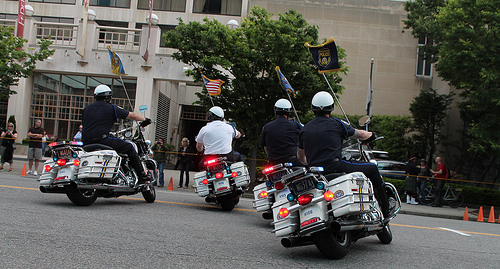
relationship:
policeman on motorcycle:
[71, 81, 152, 188] [35, 104, 159, 207]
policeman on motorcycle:
[258, 96, 305, 226] [251, 157, 311, 225]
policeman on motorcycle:
[80, 83, 157, 184] [244, 152, 441, 255]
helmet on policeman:
[273, 91, 300, 118] [264, 118, 299, 191]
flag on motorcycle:
[106, 43, 127, 76] [36, 116, 157, 207]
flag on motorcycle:
[276, 67, 298, 97] [191, 153, 251, 210]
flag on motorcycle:
[194, 70, 224, 97] [251, 159, 297, 221]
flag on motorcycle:
[106, 43, 127, 76] [269, 132, 403, 257]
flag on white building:
[11, 0, 36, 40] [1, 2, 248, 147]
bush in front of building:
[165, 6, 352, 121] [4, 1, 444, 177]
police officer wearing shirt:
[305, 105, 405, 208] [298, 112, 355, 162]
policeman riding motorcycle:
[80, 83, 157, 184] [36, 116, 157, 207]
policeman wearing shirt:
[194, 97, 243, 162] [193, 119, 240, 156]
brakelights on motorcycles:
[200, 173, 243, 180] [229, 152, 386, 247]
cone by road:
[487, 204, 496, 221] [14, 183, 254, 264]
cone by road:
[475, 205, 485, 220] [14, 183, 254, 264]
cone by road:
[462, 205, 469, 219] [14, 183, 254, 264]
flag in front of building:
[201, 74, 227, 96] [72, 5, 447, 128]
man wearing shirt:
[193, 104, 247, 204] [185, 107, 246, 170]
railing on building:
[32, 19, 82, 47] [6, 2, 423, 150]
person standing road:
[405, 154, 417, 206] [0, 176, 499, 266]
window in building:
[411, 26, 438, 81] [0, 0, 497, 183]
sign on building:
[13, 8, 33, 34] [3, 6, 484, 207]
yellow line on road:
[0, 184, 498, 237] [0, 176, 499, 266]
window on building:
[413, 28, 435, 80] [3, 6, 484, 207]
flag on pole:
[201, 74, 227, 96] [189, 58, 210, 96]